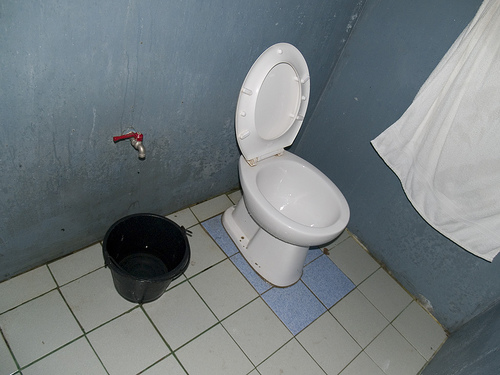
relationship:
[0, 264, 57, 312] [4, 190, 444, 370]
tile on floor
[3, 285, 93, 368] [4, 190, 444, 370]
tile on floor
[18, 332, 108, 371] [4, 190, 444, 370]
tile on floor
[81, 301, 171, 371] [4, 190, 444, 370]
tile on floor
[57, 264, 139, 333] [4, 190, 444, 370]
tile on floor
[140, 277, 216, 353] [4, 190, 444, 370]
tile on floor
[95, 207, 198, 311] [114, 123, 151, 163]
bucket underneath faucet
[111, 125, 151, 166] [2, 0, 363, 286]
faucet mounted on wall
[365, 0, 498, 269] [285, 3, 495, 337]
towel hanging on wall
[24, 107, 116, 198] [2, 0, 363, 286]
stains on wall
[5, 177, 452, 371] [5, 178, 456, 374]
tile on floor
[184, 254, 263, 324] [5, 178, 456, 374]
tile on floor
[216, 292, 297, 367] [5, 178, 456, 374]
tile on floor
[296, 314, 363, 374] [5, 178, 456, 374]
tile on floor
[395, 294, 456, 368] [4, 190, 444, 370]
tile on floor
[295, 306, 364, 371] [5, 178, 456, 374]
tile on floor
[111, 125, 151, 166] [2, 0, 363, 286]
faucet sticking out of wall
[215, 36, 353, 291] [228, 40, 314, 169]
toilet with lid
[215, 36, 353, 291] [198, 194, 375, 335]
toilet on tiles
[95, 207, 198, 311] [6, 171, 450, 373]
bucket on tiles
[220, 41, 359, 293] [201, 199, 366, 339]
toilet on tiles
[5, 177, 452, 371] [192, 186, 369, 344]
tile by tile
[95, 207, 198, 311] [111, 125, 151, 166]
bucket under faucet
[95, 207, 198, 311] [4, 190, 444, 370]
bucket sitting on floor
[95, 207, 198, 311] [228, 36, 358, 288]
bucket beside toilet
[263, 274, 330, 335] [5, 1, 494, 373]
tile on bathroom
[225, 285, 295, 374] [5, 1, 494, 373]
tile on bathroom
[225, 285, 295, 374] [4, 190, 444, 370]
tile on floor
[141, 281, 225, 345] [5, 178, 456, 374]
tile on floor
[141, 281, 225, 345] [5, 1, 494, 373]
tile on bathroom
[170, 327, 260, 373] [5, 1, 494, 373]
tile on bathroom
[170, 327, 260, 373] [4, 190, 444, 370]
tile on floor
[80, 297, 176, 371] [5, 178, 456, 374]
tile on floor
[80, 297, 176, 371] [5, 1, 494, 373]
tile on bathroom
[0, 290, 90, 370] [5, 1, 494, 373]
tile on bathroom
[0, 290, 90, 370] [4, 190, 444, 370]
tile on floor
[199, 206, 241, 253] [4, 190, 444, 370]
tile on floor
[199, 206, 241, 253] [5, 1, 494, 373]
tile on bathroom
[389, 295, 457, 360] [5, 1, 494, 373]
tile on bathroom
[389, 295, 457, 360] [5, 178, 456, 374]
tile on floor